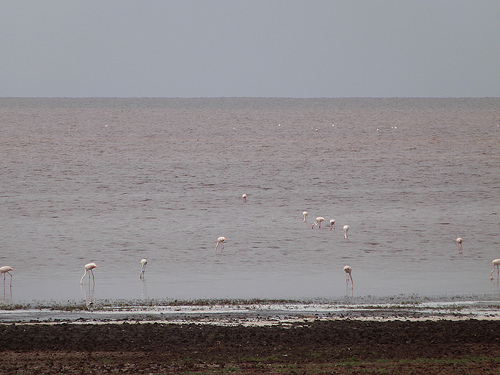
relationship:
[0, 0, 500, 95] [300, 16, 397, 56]
blue sky overhead clouds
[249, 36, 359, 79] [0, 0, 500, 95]
clouds moving blue sky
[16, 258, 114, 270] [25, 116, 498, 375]
swan near a beach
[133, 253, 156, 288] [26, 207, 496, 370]
swan near a beach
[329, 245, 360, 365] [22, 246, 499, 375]
swan near a beach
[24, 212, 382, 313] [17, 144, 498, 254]
birds in water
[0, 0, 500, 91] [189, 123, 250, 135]
clouds in blue sky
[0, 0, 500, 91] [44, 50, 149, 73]
clouds in blue sky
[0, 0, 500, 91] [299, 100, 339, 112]
clouds in blue sky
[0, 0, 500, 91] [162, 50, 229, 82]
clouds in blue sky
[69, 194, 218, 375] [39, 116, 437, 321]
these are wild birds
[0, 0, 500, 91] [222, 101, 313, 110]
clouds in blue sky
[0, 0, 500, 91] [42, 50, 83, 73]
clouds in blue sky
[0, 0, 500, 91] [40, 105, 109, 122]
clouds in blue sky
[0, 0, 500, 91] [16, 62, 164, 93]
clouds in blue sky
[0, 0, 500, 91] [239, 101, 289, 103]
clouds in blue sky